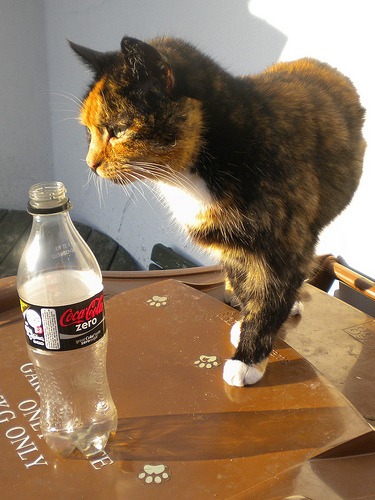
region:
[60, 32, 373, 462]
cat standing on top of something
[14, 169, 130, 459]
clear plastic coke bottle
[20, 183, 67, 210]
no lid on the bottle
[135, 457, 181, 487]
small drawing of a paw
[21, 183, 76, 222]
black ring around the top of the bottle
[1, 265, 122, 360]
label wrapped around the bottle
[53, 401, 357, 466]
shadow on the bottle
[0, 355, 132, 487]
white writing on a brown background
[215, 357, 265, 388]
the paw is white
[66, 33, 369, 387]
A tortis shell cat.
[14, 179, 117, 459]
A clear plastic bottle.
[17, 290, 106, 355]
A soda brand label.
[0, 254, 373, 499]
A wooden piece of furniture.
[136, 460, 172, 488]
A small paw print.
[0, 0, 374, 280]
A white colored wall.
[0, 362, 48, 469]
Some white colored lettering.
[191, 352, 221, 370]
A paw print sticker.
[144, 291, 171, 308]
A cream and brown pawprint.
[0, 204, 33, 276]
Part of a wood table.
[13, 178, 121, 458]
Empty plastic soda bottle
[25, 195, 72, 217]
Black plastic cap seal rim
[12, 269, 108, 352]
Soda bottle information label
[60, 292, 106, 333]
Coca Cola Zero product identification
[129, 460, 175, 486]
Cat's paw sticker on wooden top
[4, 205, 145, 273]
Old round wooden table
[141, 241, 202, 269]
Back of wooden chair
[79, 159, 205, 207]
Whiskers on house cat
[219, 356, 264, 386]
White paw on house cat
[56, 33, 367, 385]
House cat standing on wooden cart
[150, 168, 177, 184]
WHITE WHISKERS ON CAT FACE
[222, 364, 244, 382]
CAT PAW SNOW WHITE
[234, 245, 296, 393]
CAT LEG STANDING ON TABLE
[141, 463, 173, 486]
PAW PRINTED ON THE TABLE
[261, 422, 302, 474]
TABLE MADE OUT OF WOOD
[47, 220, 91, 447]
COKE BOTTLE ON THE TABLE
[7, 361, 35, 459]
WORDS PRINTED IN WHITE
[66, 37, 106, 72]
CAT EAR STANDING OUT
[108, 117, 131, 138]
CAT EYE WIDE OPEN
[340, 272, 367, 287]
HANDLE MADE OUT OF WOOD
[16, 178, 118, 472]
an empty coke bottle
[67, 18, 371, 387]
an orange and black cat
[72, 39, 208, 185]
the face of the cat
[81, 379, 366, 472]
shadow of the bottle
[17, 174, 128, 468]
a bottle of coke zero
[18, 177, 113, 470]
empty bottle of coke zero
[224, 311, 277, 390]
the cat's white front paws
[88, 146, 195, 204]
white whisker's of the cat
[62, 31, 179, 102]
ears of the cat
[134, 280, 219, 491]
three little white pawprints